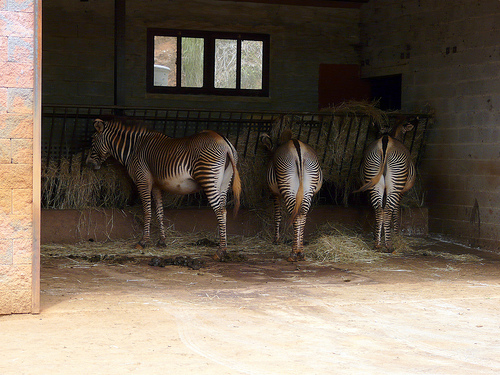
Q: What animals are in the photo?
A: Zebra.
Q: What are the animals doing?
A: Eating.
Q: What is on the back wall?
A: Window.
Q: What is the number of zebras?
A: Three.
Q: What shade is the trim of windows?
A: Dark shade.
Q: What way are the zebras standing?
A: Butts pointed out.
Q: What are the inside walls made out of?
A: Grey cinder blocks.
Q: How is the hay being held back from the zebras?
A: Black steel rail with slats in it hung diagonally.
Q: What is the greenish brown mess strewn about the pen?
A: Zebra poop.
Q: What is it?
A: Zebras.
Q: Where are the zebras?
A: On the ground.